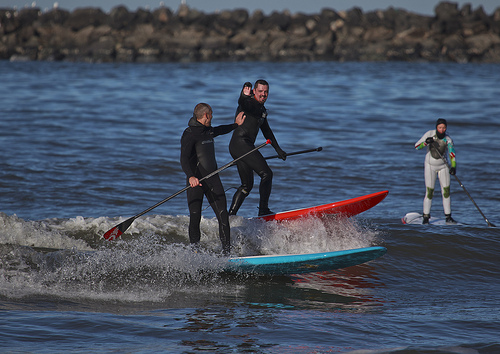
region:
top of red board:
[362, 184, 390, 213]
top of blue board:
[348, 236, 390, 275]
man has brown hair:
[195, 101, 205, 115]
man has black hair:
[258, 76, 265, 85]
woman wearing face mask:
[437, 114, 445, 126]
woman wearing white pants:
[423, 161, 432, 181]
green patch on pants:
[428, 187, 433, 198]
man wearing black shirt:
[183, 139, 191, 164]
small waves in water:
[327, 90, 370, 134]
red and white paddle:
[98, 224, 125, 243]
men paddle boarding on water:
[72, 16, 462, 346]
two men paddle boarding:
[104, 11, 396, 271]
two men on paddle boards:
[122, 42, 494, 287]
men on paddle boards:
[112, 52, 428, 329]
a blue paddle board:
[65, 63, 349, 351]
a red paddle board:
[155, 57, 425, 264]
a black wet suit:
[148, 4, 358, 299]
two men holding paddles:
[141, 25, 378, 277]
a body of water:
[18, 57, 163, 227]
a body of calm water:
[61, 77, 156, 195]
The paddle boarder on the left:
[178, 98, 248, 265]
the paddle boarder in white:
[411, 103, 466, 225]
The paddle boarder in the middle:
[224, 70, 291, 222]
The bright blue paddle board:
[216, 238, 388, 278]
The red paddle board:
[254, 185, 391, 227]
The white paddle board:
[399, 206, 468, 231]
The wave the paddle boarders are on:
[1, 208, 499, 300]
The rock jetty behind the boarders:
[0, 2, 498, 70]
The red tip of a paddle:
[260, 134, 272, 151]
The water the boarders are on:
[1, 60, 498, 352]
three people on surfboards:
[165, 66, 469, 318]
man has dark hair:
[184, 98, 211, 126]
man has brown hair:
[243, 71, 278, 101]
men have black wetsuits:
[175, 91, 287, 226]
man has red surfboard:
[263, 186, 382, 226]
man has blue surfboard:
[157, 249, 385, 277]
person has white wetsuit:
[417, 113, 462, 223]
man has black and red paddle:
[92, 141, 268, 247]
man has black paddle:
[260, 140, 355, 168]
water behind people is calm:
[39, 83, 150, 194]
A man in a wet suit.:
[179, 101, 247, 256]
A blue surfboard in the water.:
[226, 243, 388, 275]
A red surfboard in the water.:
[251, 187, 389, 223]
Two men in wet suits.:
[178, 78, 288, 255]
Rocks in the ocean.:
[1, 0, 498, 64]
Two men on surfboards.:
[179, 78, 389, 278]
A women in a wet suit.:
[413, 117, 458, 226]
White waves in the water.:
[1, 211, 385, 303]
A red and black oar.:
[101, 136, 270, 243]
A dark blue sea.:
[0, 60, 498, 348]